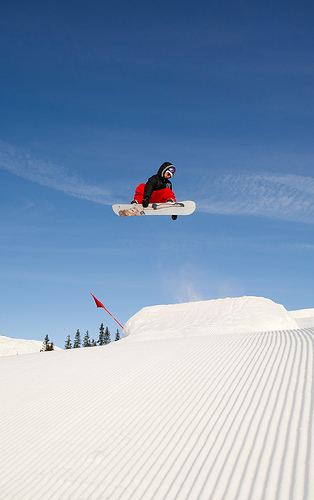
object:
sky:
[0, 0, 314, 352]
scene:
[0, 0, 313, 498]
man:
[129, 158, 177, 221]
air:
[0, 0, 314, 347]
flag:
[89, 290, 123, 328]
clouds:
[0, 144, 314, 226]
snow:
[0, 294, 314, 499]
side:
[0, 295, 314, 497]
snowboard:
[110, 198, 197, 217]